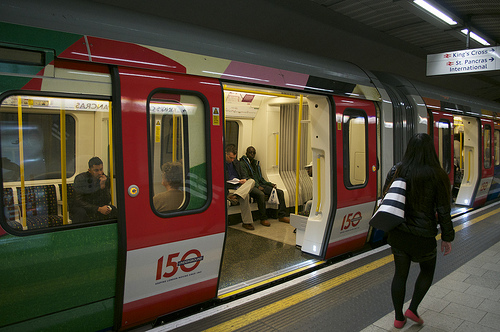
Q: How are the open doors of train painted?
A: Red and white.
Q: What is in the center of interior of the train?
A: Yellow bars.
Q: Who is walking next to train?
A: A woman.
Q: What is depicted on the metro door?
A: London underground.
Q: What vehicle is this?
A: A train.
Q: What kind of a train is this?
A: A subway train.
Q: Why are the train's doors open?
A: It's at a station.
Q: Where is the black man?
A: Inside the train.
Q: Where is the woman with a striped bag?
A: Next to the train.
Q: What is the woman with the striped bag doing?
A: Walking.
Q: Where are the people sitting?
A: Inside the train car.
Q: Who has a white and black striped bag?
A: The woman at the station.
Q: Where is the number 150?
A: On the train doors.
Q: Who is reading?
A: The man in the train.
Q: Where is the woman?
A: Outside of the train door.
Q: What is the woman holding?
A: A white and black striped bag.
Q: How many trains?
A: 1.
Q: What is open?
A: Train.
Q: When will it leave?
A: Soon.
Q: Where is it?
A: On the tracks.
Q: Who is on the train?
A: People.